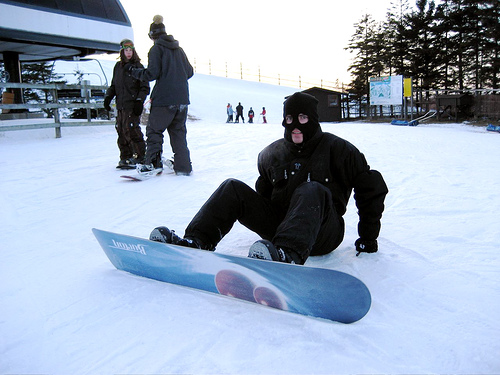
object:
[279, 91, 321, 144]
mask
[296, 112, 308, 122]
eye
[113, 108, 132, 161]
leg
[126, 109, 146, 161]
leg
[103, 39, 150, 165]
person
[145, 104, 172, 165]
leg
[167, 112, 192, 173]
leg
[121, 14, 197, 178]
person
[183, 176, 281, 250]
leg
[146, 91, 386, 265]
man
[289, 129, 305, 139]
mouth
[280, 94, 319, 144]
head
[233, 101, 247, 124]
people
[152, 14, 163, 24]
pompom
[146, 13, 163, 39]
hat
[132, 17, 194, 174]
guy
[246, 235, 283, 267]
foot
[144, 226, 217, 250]
feet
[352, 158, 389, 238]
arm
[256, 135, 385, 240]
jacket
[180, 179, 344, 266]
pants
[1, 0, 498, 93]
distance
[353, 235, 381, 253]
hand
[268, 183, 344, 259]
leg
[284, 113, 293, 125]
eye